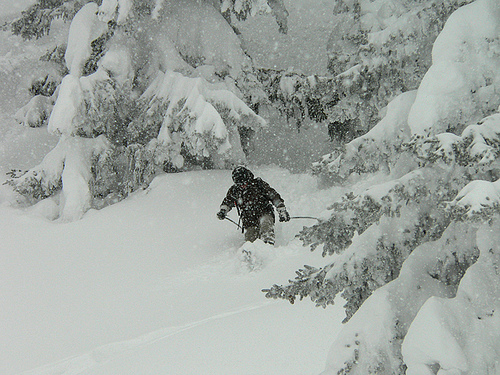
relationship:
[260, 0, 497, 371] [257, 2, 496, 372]
tree covered with snow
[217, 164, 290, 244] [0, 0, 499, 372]
man walking through snow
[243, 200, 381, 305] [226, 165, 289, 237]
pants on person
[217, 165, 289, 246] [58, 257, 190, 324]
person skiing in thick snow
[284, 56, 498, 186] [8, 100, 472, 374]
tree completely covered in snow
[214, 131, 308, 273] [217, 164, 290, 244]
ski pants on a man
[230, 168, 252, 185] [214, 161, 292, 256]
goggles on a man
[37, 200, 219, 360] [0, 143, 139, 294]
snow on hill side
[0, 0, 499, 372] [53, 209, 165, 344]
snow on hill side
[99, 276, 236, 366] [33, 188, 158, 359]
snow on hill side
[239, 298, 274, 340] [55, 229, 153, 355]
snow on hill side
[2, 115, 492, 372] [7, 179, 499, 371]
snow on hill side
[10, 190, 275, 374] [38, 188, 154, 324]
snow on hill side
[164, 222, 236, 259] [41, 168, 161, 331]
snow on hill side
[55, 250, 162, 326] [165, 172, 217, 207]
snow on hill side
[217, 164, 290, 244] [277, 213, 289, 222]
man wearing heavy coat and glove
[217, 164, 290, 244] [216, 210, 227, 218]
man wearing heavy coat and glove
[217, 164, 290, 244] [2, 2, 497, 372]
man walking through blizzard in woods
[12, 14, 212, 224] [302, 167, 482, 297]
tree with snow on limbs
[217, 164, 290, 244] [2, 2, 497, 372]
man walking through deep snow in woods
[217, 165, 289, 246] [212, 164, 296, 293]
person wearing heavy coat and snow boots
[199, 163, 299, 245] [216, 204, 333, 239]
man holds sticks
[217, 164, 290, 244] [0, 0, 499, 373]
man in wooded area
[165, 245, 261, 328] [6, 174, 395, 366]
snow on ground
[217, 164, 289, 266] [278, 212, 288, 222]
person has hand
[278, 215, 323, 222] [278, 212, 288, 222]
ski pole on hand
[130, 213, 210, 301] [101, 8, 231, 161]
snow on tree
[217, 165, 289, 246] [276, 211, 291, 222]
person wears glove